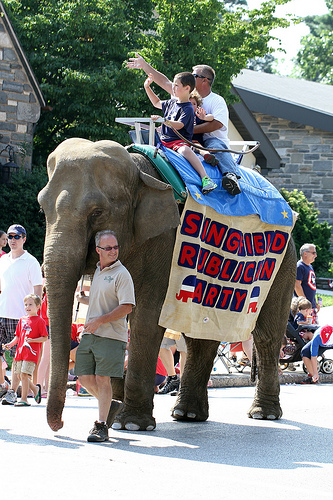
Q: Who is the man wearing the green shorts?
A: Elephant handler.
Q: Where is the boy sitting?
A: On the elephant.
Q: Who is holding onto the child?
A: Man on top of elephant.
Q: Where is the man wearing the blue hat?
A: Next to child in red.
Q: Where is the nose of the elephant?
A: It is known as a trunk.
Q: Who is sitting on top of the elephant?
A: Three people.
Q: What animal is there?
A: Elephant.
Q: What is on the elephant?
A: Banner.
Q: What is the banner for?
A: Republican party.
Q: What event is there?
A: Parade.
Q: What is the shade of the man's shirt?
A: White.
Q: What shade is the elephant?
A: Gray.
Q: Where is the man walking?
A: Near elephant.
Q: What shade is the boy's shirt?
A: Blue.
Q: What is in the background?
A: Buildings.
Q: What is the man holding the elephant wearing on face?
A: Sunglasses.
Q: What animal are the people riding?
A: Elephant.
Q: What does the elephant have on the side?
A: Banner.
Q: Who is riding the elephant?
A: Boy.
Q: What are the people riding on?
A: Elephant.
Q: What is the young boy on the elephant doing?
A: Waving.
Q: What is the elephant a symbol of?
A: Republican party.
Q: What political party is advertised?
A: Republican party.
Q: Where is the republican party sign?
A: On the elephant.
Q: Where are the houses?
A: Behind the bushes.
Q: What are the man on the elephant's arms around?
A: A young child.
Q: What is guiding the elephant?
A: A man.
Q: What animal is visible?
A: Elephant.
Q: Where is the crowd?
A: On the curb.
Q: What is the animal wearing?
A: A banner.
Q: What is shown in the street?
A: A shadow.